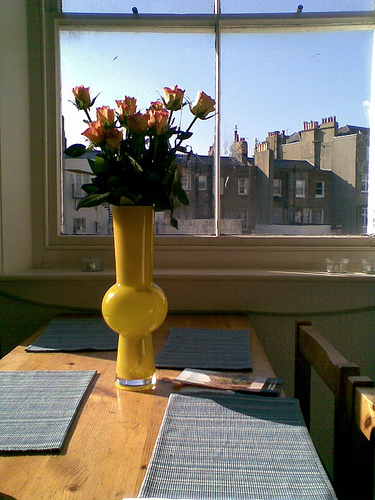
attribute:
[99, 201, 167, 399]
vase — tall, yellow, cylindrical, large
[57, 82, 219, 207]
boquet — roses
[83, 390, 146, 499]
table — wooden, wood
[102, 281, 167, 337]
bulge — round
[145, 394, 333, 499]
placemat — wooven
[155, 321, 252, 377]
placemat — blue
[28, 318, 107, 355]
placemat — blue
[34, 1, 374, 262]
window — painted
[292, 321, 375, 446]
chairs — wooden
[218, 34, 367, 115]
sky — blue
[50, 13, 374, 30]
frame — cream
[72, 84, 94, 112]
flower — pink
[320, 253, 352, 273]
holder — glass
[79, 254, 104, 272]
holder — glass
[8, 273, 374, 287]
sill — wood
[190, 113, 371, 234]
building — brick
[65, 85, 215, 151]
roses — pink, red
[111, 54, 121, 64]
bird — flying